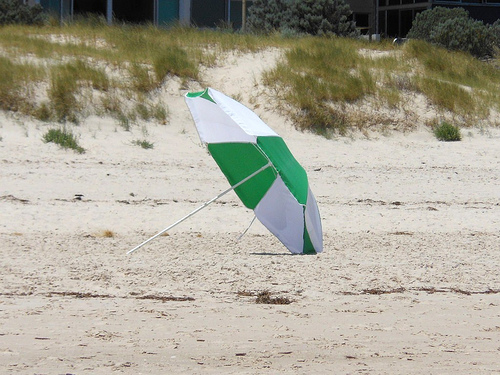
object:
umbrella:
[187, 89, 321, 256]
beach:
[0, 147, 498, 373]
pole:
[125, 162, 270, 255]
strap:
[238, 216, 255, 239]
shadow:
[250, 253, 317, 255]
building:
[0, 0, 500, 41]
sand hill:
[0, 26, 499, 139]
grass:
[0, 22, 500, 154]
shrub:
[431, 17, 492, 55]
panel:
[207, 142, 277, 208]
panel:
[255, 136, 308, 203]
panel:
[186, 87, 216, 103]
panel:
[305, 187, 324, 254]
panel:
[209, 88, 279, 137]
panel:
[186, 96, 257, 142]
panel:
[254, 175, 304, 254]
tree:
[0, 0, 43, 27]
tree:
[243, 0, 356, 35]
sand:
[0, 232, 500, 373]